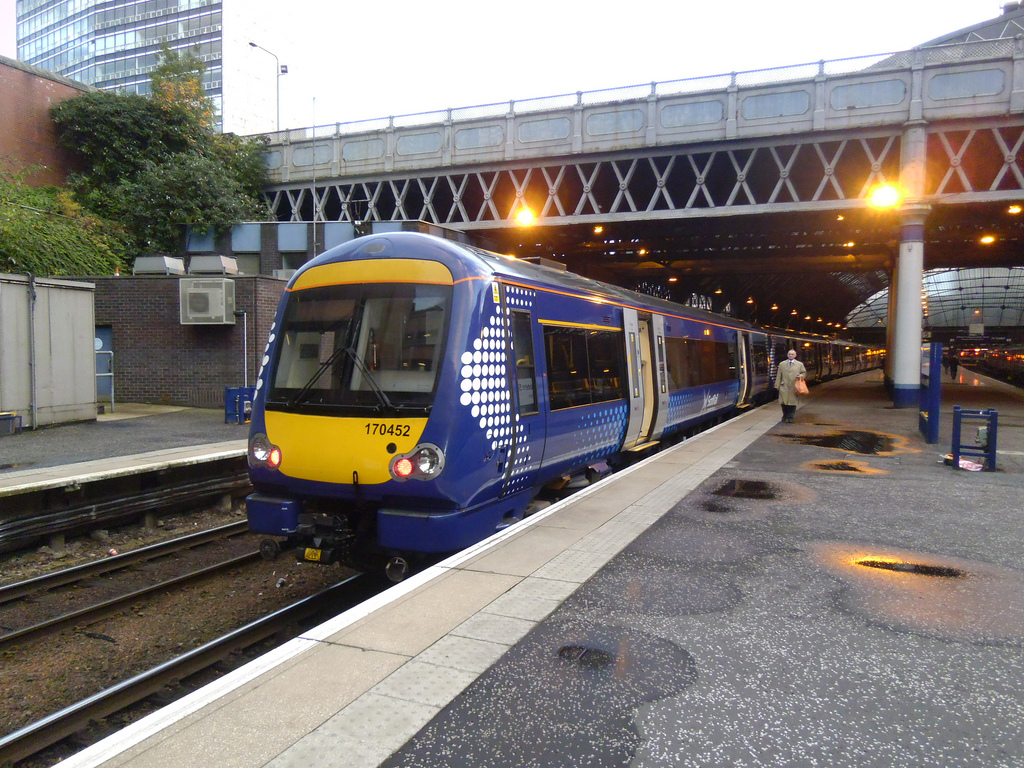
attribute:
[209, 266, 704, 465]
train — yellow, white, blue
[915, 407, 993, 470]
bars — blue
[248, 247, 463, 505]
train — yellow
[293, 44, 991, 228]
bridge — white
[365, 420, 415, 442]
numbers — 170452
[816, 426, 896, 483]
puddle — large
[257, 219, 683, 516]
train — blue, yellow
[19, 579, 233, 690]
track — train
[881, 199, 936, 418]
column — blue, white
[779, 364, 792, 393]
coat — rain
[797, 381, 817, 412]
bag — orange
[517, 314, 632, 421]
window — long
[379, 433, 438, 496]
headlight — round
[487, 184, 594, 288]
light — orange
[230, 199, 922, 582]
train — blue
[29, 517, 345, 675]
tracks — yellow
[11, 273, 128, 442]
doors — sliding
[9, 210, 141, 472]
shed — biege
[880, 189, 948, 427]
column — white, large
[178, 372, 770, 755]
stripe — white